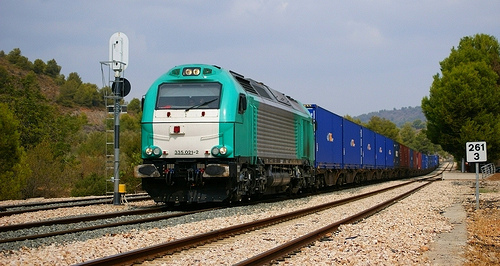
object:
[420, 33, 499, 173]
tree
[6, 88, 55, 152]
tree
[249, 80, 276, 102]
window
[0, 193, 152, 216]
track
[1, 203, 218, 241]
track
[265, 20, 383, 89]
blue sky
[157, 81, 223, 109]
windshield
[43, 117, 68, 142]
leaves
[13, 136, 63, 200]
tree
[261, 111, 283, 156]
ground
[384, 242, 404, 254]
rocks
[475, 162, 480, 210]
pole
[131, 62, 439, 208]
train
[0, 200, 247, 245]
middle tracks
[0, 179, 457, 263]
gravel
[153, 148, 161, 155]
headlight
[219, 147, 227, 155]
headlight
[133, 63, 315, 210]
engine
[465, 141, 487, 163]
sign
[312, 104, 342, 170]
blue cars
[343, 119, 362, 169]
blue cars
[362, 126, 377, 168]
blue cars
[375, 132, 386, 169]
blue cars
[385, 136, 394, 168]
blue cars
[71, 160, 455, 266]
rail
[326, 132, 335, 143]
logo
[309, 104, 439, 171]
freight cars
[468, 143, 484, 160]
261 3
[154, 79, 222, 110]
window